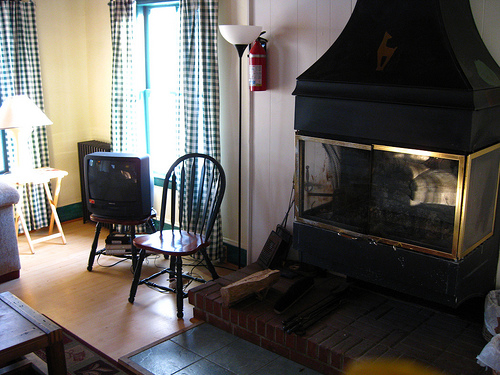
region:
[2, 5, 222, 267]
long blue and white curtains by windows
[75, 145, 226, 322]
wooden chair next to television set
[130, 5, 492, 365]
huge black and gold fireplace and hearth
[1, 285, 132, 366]
wooden and reflective surface of furniture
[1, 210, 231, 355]
light-colored wood covering floor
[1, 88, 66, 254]
standing lamp on top of open folding table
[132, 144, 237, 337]
Chair on wood floor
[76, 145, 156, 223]
TV on a stand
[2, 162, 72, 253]
End table by a chair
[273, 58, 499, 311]
Black and gold fireplace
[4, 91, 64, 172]
Lamp on a table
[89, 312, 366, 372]
Tile by a fireplace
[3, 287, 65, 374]
Table in a living room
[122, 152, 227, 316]
a black and brown wooden chair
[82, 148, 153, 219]
a small black TV set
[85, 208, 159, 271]
a black and brown wooden stool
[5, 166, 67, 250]
a brown folding table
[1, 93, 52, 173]
a short table lamp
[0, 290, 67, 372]
a brown wood table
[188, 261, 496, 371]
a red brick hearth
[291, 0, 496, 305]
a black metal fire place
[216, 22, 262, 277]
a black floor lamp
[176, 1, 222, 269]
a blue and white checkered curtain panel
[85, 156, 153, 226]
the tv is small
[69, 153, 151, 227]
the tv is small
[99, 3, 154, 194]
the curtain is plaid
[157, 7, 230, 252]
the curtain is plaid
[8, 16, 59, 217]
the curtain is plaid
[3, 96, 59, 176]
the lamp is white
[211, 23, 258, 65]
the light is white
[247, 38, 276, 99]
the fire extinguisher is red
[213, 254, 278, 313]
the wood is cut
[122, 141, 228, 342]
brown wooden chair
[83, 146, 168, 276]
box television set on stool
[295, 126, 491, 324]
wood burning glass enclosure in black and gold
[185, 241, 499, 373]
brick flooring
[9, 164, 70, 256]
small foldable wooden table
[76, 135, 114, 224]
black space heater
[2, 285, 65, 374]
wooden table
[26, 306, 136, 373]
corner of a floral patterned rug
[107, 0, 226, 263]
Green and white checkered curtains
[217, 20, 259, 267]
Floor lamp with white shade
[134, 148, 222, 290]
the chair is empty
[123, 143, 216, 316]
the chair is empty